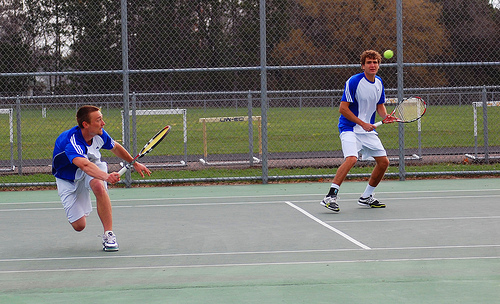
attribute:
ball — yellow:
[382, 47, 393, 61]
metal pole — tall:
[240, 25, 317, 175]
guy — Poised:
[321, 45, 435, 220]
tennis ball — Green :
[381, 45, 397, 61]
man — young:
[313, 46, 430, 212]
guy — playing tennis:
[47, 104, 157, 256]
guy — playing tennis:
[319, 48, 400, 213]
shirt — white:
[341, 71, 400, 137]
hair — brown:
[359, 50, 382, 66]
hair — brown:
[75, 105, 102, 128]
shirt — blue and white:
[335, 72, 388, 132]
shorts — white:
[59, 163, 101, 221]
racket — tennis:
[112, 103, 204, 175]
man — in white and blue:
[270, 38, 415, 221]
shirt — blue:
[45, 119, 119, 198]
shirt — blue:
[316, 62, 421, 151]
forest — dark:
[6, 5, 484, 101]